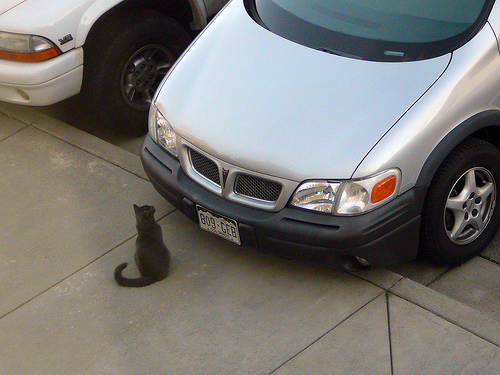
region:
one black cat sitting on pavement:
[109, 199, 173, 297]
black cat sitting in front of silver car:
[83, 82, 448, 323]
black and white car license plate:
[188, 202, 253, 248]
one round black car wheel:
[428, 129, 499, 271]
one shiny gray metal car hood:
[152, 6, 462, 187]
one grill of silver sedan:
[173, 141, 288, 216]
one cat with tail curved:
[113, 199, 176, 294]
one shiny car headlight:
[283, 177, 341, 214]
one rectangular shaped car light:
[368, 171, 399, 207]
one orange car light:
[369, 172, 399, 207]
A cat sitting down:
[109, 195, 178, 295]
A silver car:
[143, 0, 499, 264]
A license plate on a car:
[192, 200, 251, 247]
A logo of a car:
[215, 162, 235, 194]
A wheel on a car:
[418, 156, 498, 263]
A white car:
[1, 1, 207, 129]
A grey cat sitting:
[105, 198, 177, 297]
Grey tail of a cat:
[111, 261, 155, 288]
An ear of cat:
[126, 199, 140, 211]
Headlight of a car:
[296, 175, 374, 215]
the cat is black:
[70, 177, 175, 303]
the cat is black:
[97, 180, 177, 290]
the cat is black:
[100, 185, 175, 305]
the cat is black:
[100, 205, 172, 300]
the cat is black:
[100, 185, 205, 320]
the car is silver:
[110, 47, 440, 267]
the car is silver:
[130, 67, 370, 234]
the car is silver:
[131, 50, 406, 237]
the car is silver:
[140, 32, 390, 302]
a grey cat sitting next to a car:
[108, 197, 170, 291]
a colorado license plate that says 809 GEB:
[186, 197, 244, 252]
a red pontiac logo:
[215, 158, 237, 190]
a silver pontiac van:
[136, 0, 498, 277]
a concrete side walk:
[1, 85, 498, 370]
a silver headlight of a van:
[279, 166, 410, 217]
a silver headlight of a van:
[140, 101, 183, 156]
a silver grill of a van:
[178, 134, 295, 218]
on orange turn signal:
[368, 170, 403, 203]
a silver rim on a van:
[436, 151, 497, 256]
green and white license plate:
[196, 208, 240, 246]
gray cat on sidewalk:
[112, 204, 169, 286]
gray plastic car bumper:
[140, 132, 424, 268]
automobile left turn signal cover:
[369, 175, 395, 202]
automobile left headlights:
[291, 178, 367, 214]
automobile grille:
[181, 142, 299, 211]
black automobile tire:
[80, 5, 197, 136]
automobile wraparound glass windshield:
[241, 0, 446, 61]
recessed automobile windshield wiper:
[320, 45, 367, 57]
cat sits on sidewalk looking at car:
[110, 0, 495, 294]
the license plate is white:
[193, 206, 242, 247]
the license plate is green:
[194, 203, 241, 250]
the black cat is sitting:
[111, 205, 172, 286]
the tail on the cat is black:
[112, 261, 150, 291]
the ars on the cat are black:
[132, 203, 152, 215]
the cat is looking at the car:
[115, 203, 172, 290]